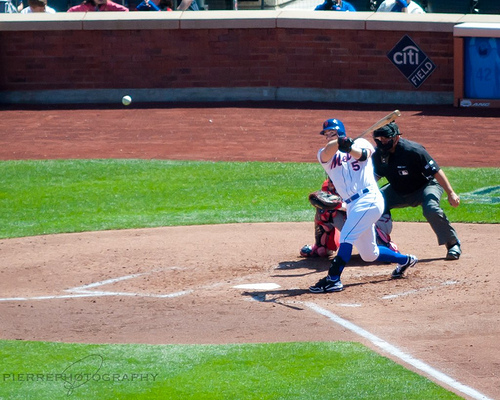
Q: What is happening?
A: The ball was hit.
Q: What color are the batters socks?
A: Blue.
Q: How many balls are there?
A: One.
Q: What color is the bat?
A: Brown.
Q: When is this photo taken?
A: Daytime.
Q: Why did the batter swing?
A: To hit the ball.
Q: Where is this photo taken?
A: A baseball field.